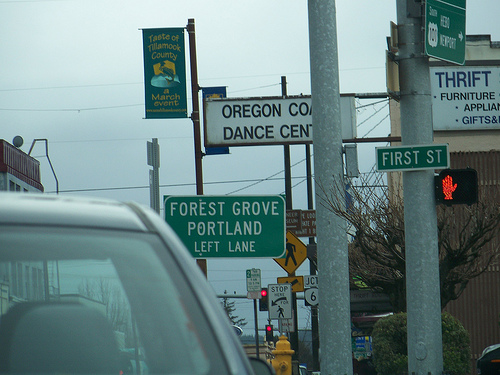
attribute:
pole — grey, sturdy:
[396, 0, 444, 374]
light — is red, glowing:
[261, 289, 267, 296]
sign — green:
[162, 194, 287, 260]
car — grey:
[0, 191, 248, 373]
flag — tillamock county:
[143, 28, 187, 120]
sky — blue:
[0, 0, 499, 337]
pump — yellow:
[273, 336, 294, 374]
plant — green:
[373, 311, 404, 374]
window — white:
[7, 173, 17, 191]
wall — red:
[435, 149, 500, 374]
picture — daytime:
[0, 2, 498, 372]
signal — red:
[259, 287, 268, 310]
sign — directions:
[423, 1, 468, 65]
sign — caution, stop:
[269, 229, 310, 273]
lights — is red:
[259, 286, 273, 341]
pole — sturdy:
[306, 1, 354, 373]